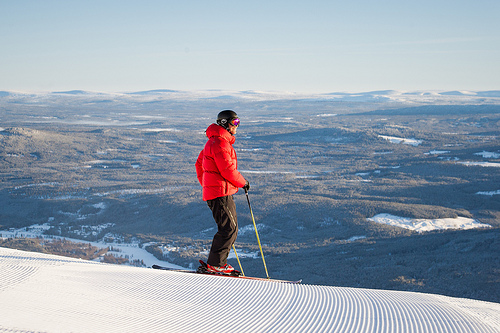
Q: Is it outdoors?
A: Yes, it is outdoors.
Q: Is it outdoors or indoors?
A: It is outdoors.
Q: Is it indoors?
A: No, it is outdoors.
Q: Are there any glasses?
A: No, there are no glasses.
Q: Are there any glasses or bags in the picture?
A: No, there are no glasses or bags.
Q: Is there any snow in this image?
A: Yes, there is snow.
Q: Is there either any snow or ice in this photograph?
A: Yes, there is snow.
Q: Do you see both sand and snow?
A: No, there is snow but no sand.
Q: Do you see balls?
A: No, there are no balls.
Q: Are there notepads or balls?
A: No, there are no balls or notepads.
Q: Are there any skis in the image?
A: Yes, there are skis.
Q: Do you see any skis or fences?
A: Yes, there are skis.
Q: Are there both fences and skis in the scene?
A: No, there are skis but no fences.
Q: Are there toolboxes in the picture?
A: No, there are no toolboxes.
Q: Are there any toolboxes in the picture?
A: No, there are no toolboxes.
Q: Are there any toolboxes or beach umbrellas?
A: No, there are no toolboxes or beach umbrellas.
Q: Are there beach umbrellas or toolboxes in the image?
A: No, there are no toolboxes or beach umbrellas.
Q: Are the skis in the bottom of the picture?
A: Yes, the skis are in the bottom of the image.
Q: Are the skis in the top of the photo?
A: No, the skis are in the bottom of the image.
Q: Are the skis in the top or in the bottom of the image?
A: The skis are in the bottom of the image.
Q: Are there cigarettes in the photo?
A: No, there are no cigarettes.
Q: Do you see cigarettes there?
A: No, there are no cigarettes.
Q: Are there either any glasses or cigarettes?
A: No, there are no cigarettes or glasses.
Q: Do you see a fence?
A: No, there are no fences.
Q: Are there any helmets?
A: Yes, there is a helmet.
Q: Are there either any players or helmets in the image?
A: Yes, there is a helmet.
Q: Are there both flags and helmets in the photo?
A: No, there is a helmet but no flags.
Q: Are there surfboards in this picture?
A: No, there are no surfboards.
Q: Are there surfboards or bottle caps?
A: No, there are no surfboards or bottle caps.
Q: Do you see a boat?
A: No, there are no boats.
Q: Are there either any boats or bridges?
A: No, there are no boats or bridges.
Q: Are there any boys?
A: No, there are no boys.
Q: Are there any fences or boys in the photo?
A: No, there are no boys or fences.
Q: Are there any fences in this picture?
A: No, there are no fences.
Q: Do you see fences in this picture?
A: No, there are no fences.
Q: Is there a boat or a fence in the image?
A: No, there are no fences or boats.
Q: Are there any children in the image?
A: No, there are no children.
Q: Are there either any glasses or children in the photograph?
A: No, there are no children or glasses.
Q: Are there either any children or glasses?
A: No, there are no children or glasses.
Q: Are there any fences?
A: No, there are no fences.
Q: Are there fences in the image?
A: No, there are no fences.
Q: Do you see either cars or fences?
A: No, there are no fences or cars.